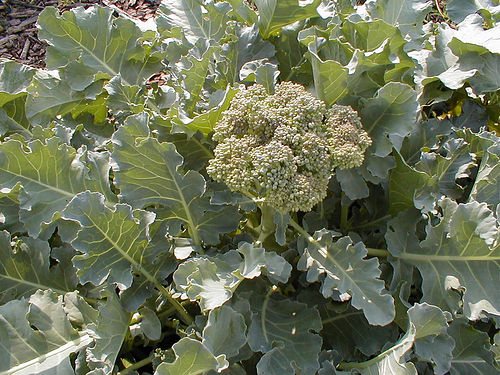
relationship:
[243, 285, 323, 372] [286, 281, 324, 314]
leaf in shade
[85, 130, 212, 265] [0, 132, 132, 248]
leaf next to large leaf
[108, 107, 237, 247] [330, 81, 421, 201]
leaf next to large leaf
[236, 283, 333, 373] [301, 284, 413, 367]
leaf next to large leaf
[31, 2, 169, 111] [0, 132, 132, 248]
leaf next to large leaf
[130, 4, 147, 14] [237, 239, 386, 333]
sticks on side of leaves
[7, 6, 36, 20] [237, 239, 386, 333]
sticks on side of leaves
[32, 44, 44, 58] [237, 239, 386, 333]
sticks on side of leaves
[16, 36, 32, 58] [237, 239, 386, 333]
sticks on side of leaves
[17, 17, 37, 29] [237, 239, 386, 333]
sticks on side of leaves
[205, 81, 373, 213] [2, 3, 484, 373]
brocolli surrounded a bunch of large leaves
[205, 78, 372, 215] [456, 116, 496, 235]
plant growing in middle of green leaves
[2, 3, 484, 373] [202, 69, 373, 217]
leaves growing around cauliflower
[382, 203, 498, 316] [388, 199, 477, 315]
green leaf on leaf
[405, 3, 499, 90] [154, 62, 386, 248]
leaves surrounding broccoli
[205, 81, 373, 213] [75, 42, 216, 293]
brocolli growing on a tree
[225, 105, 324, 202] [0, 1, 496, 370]
brocolli on a bush